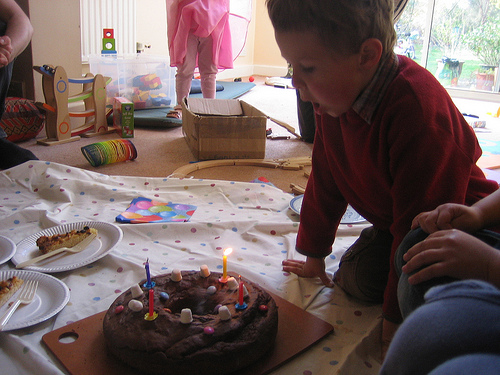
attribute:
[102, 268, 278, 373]
cake — round, chocolate, circular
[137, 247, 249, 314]
candles — lit, yellow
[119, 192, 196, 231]
napkins — paper, colorful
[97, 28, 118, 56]
blocks — red, green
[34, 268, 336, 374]
plate — wooden, white, rectangular, paper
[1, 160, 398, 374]
polka dots — colorful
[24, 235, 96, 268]
fork — white, plastic, off white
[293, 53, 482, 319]
shirt — maroon, red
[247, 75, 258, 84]
ball — red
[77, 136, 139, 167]
toy — rainbow, slinky, colorful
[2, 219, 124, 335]
plates — paper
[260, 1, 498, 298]
boy — blowing, young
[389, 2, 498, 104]
doors — sliding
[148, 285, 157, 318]
candle — red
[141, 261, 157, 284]
candlei — blue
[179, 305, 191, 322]
marshmallow — fluffy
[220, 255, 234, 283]
candle — yellow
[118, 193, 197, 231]
napkin — colorful